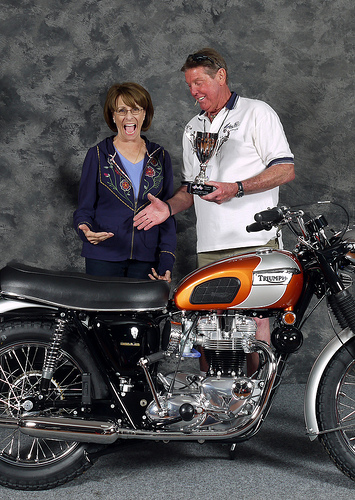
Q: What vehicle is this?
A: A motorcycle.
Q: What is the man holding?
A: A trophy.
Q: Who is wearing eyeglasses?
A: The woman.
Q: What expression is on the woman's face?
A: Shock.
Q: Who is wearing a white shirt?
A: The man.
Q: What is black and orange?
A: The motorcycle.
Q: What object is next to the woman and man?
A: A motorcycle.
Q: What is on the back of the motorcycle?
A: A wheel.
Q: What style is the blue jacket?
A: Decorated.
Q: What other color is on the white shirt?
A: Blue.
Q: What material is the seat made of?
A: Leather.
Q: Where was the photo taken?
A: Next to bike.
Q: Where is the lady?
A: Next to bike.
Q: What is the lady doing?
A: Standing.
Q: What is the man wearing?
A: White shirt.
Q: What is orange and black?
A: The bike.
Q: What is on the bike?
A: Tires.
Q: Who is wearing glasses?
A: The woman.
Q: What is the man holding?
A: Trophy.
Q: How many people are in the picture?
A: Two.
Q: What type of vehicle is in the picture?
A: Motercycle.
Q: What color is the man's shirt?
A: White.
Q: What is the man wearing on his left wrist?
A: A watch.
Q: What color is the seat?
A: Black.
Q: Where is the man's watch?
A: Wrist.